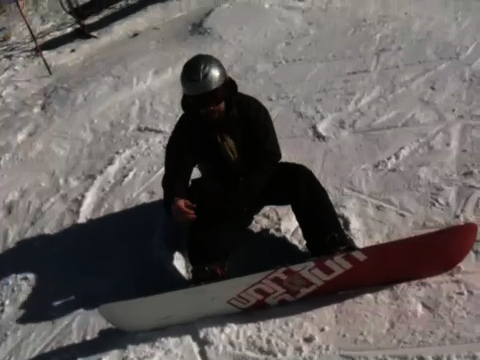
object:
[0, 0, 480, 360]
tracks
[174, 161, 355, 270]
legs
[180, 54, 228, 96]
helmet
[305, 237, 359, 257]
boot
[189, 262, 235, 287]
foot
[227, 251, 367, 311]
logo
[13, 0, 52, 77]
pole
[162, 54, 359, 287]
man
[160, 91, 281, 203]
coat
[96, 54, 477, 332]
snow suit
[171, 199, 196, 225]
hand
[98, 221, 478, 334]
side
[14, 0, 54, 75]
stick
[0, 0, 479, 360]
ground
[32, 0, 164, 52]
shadow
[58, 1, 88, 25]
stick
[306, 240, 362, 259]
foot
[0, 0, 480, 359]
snow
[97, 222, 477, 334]
snowboard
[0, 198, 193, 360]
shadow